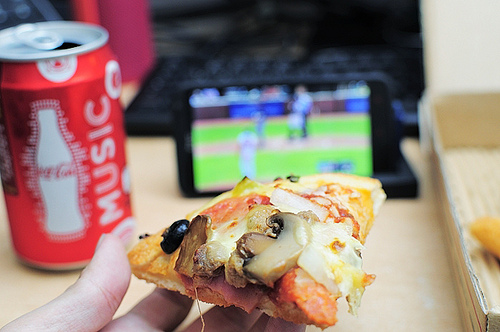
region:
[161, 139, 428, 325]
a pizza being held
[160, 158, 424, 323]
a slice of pizza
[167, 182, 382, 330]
a slice of pizza being held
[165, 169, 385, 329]
a cooked slice of pizza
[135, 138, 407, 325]
a baked slice of pizza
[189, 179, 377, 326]
a pizza with mushrooms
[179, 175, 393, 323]
a cooked pizza with mushroom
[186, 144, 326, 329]
a pizza with pepporini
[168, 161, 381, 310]
a pizza with olives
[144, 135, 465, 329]
a pizza with black olives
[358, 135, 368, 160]
part of a screen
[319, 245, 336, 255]
part of a pizza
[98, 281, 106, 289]
part of a plate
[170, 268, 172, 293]
part of a finger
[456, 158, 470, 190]
part of a finger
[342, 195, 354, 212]
part of a pizza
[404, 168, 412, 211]
part of a table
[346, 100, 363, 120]
part of a screen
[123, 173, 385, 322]
triangular shaped slice of pizza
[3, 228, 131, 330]
thumb touching pizza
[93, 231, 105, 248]
fingernail on thumb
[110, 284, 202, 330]
finger under pizza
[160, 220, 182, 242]
black olive piece piece on top of pizza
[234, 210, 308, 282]
mushroom slice on top of pizza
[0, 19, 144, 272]
red aluminum can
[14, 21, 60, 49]
pop tab on top of aluminum can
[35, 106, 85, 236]
image of a soda bottle printed on can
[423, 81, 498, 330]
cardboard box to the right of pizza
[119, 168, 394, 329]
a supreme slice of pizza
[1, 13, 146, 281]
a can of coca cola that says music on it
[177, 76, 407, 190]
a baseball game being watched on a phone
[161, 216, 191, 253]
a black olive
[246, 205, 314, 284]
a mushroom topping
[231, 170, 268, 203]
a yellow pepper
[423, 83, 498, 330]
a cardboard box top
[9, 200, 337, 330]
a white hand with some pizza in it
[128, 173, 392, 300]
white cheese on pizza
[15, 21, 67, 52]
a silver can tab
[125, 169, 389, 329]
Small slice of pizza loaded with toppings.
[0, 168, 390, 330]
A hand holding pizza.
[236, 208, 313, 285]
Slice of mushroom.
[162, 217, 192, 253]
A black olive.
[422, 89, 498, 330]
Cardboard pizza box.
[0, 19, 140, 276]
Open can of Coca Cola.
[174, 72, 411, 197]
Baseball game on a cell phone.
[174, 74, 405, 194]
Black cell phone.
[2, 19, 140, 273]
Red can with top opened.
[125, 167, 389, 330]
Slice of pizza topped with vegetables and meats.